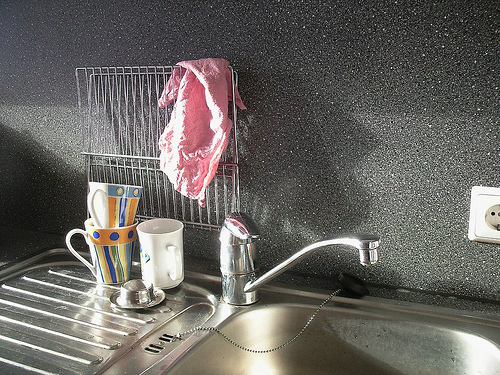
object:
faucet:
[219, 212, 381, 306]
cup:
[66, 218, 138, 285]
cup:
[86, 182, 142, 228]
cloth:
[158, 57, 248, 209]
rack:
[75, 66, 238, 233]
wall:
[0, 0, 499, 303]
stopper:
[338, 273, 367, 296]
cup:
[136, 218, 185, 290]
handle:
[66, 228, 97, 277]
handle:
[87, 189, 103, 228]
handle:
[167, 244, 181, 281]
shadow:
[98, 63, 381, 237]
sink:
[148, 303, 500, 375]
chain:
[171, 288, 342, 353]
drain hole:
[145, 348, 159, 354]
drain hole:
[150, 344, 164, 349]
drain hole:
[159, 337, 170, 342]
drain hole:
[163, 334, 173, 338]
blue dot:
[110, 232, 120, 241]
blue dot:
[93, 231, 100, 238]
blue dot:
[128, 230, 133, 238]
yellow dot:
[116, 188, 123, 196]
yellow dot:
[133, 189, 139, 197]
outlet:
[468, 186, 500, 245]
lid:
[110, 279, 165, 309]